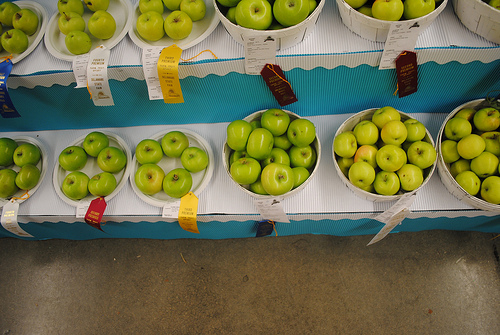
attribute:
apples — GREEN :
[135, 130, 206, 196]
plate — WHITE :
[130, 129, 213, 209]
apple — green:
[379, 116, 409, 148]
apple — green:
[404, 136, 438, 172]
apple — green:
[348, 160, 377, 190]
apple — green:
[157, 125, 186, 163]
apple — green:
[233, 5, 269, 28]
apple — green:
[264, 145, 289, 166]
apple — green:
[444, 111, 473, 141]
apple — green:
[157, 127, 187, 159]